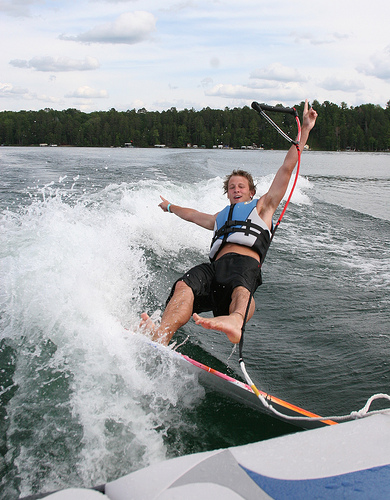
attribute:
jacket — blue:
[209, 204, 265, 242]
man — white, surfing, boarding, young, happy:
[143, 104, 315, 333]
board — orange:
[144, 343, 279, 415]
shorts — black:
[185, 254, 264, 297]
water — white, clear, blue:
[17, 165, 151, 385]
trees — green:
[25, 99, 236, 144]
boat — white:
[133, 425, 382, 500]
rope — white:
[232, 356, 368, 422]